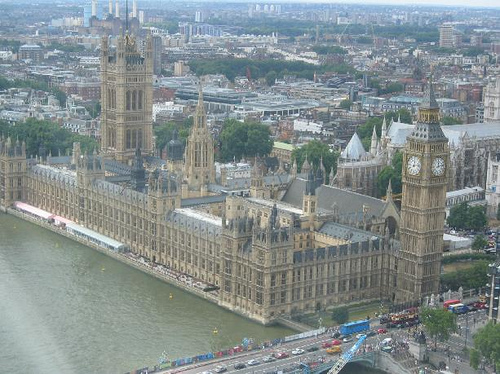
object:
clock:
[430, 157, 446, 178]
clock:
[406, 157, 421, 174]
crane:
[318, 331, 380, 374]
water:
[0, 209, 305, 371]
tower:
[98, 29, 157, 165]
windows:
[203, 242, 215, 255]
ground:
[356, 326, 412, 350]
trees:
[0, 107, 100, 157]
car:
[292, 348, 306, 355]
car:
[326, 345, 341, 354]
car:
[230, 361, 245, 369]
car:
[262, 355, 277, 363]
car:
[331, 339, 342, 346]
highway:
[134, 288, 499, 372]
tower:
[186, 80, 216, 185]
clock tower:
[399, 77, 451, 306]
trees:
[220, 114, 282, 171]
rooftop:
[47, 154, 395, 252]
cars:
[245, 357, 258, 366]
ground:
[270, 68, 325, 105]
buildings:
[0, 26, 500, 327]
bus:
[443, 300, 459, 309]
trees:
[417, 298, 499, 369]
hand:
[436, 158, 439, 168]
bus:
[341, 319, 371, 336]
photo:
[0, 0, 499, 371]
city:
[0, 0, 500, 373]